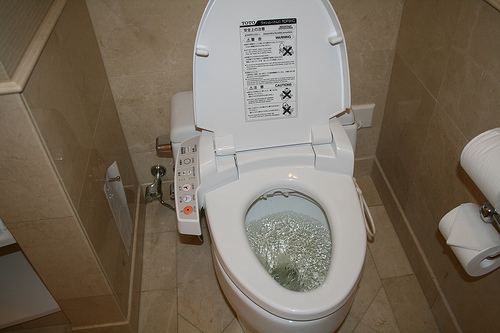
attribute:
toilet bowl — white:
[210, 166, 372, 302]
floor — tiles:
[141, 163, 454, 330]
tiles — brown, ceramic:
[141, 125, 450, 325]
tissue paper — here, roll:
[439, 132, 500, 280]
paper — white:
[437, 130, 499, 286]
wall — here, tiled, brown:
[353, 0, 498, 324]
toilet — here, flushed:
[167, 0, 417, 321]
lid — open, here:
[187, 3, 378, 182]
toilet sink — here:
[242, 186, 341, 301]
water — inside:
[245, 206, 332, 288]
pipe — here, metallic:
[146, 164, 171, 210]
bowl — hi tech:
[171, 128, 375, 313]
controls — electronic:
[174, 142, 200, 224]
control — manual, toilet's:
[150, 130, 172, 155]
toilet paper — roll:
[457, 123, 499, 213]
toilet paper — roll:
[436, 198, 496, 280]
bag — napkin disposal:
[98, 150, 139, 264]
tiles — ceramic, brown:
[4, 0, 500, 316]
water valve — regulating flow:
[143, 161, 168, 204]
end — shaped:
[439, 211, 482, 253]